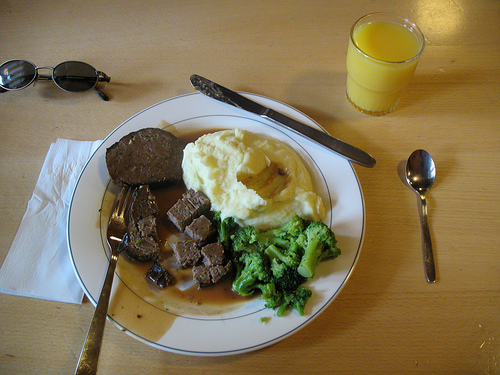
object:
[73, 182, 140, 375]
fork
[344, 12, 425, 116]
cup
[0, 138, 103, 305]
napkin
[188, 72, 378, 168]
butter knife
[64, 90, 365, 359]
plate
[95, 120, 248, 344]
gravy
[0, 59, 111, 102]
glasses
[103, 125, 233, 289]
meat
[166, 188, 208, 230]
liver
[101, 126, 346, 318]
food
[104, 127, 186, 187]
meatloaf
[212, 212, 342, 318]
broccoli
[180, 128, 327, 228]
potato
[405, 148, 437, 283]
spoon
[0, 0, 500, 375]
table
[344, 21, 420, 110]
juice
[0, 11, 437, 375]
items